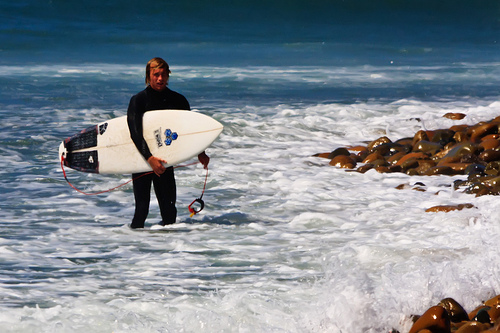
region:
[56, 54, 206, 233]
man carrying white surf board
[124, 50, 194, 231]
man wearing black wet suit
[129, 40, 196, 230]
surfer wearing wet suit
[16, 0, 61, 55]
white clouds in blue sky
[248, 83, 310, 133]
blue and white ocean waves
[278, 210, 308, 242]
blue and white ocean waves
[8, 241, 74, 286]
blue and white ocean waves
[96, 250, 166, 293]
blue and white ocean waves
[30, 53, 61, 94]
blue and white ocean waves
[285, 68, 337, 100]
blue and white ocean waves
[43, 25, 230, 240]
A surfer standing in surf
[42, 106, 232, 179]
Black and white surfboard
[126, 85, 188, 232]
A black surfer holding surf board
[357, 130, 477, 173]
Rocks in the surf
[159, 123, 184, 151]
Blue design on surfboard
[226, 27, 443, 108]
Blue and white sea water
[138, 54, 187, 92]
A man with blonde hair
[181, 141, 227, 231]
Surfboard safety line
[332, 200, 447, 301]
White foam from the surf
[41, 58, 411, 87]
White foamy surf in background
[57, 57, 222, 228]
man carrying his surfboard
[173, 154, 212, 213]
leg rope detached from man's leg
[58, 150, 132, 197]
leg rope attached to surfboard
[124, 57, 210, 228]
man wearing a wet suit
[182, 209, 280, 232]
shadow of the man in the water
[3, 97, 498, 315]
foam on top of the ocean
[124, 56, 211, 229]
man with blond wet hair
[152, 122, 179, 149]
markings on the surfboard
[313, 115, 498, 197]
rocks jutting into the sea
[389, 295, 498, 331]
a small area of rocks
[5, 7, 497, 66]
The water is blue.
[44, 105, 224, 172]
The surf board is white.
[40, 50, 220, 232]
He is in the water.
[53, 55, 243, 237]
He is walking in the water.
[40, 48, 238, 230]
He was holding the surf board.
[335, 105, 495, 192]
The shore has rocks.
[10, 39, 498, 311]
The waves are crashing on the rocks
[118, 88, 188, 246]
He is wearing a wet suit.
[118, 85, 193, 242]
His wet suit is black.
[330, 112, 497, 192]
The rocks are brown.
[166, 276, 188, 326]
Ripples in the water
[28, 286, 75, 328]
Ripples in the water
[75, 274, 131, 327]
Ripples in the water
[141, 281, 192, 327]
Ripples in the water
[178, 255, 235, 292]
Ripples in the water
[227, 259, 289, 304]
Ripples in the water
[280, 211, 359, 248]
Ripples in the water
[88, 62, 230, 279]
Person in black wet suite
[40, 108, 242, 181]
White color surf board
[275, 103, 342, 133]
Ripples in the water